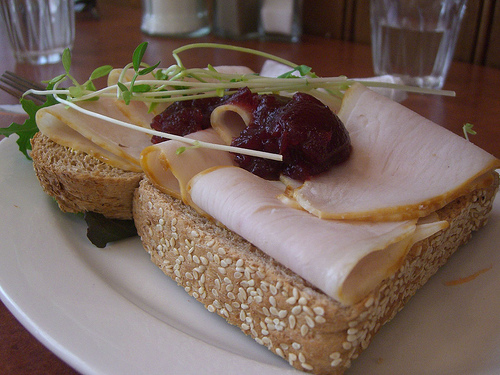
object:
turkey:
[154, 84, 305, 123]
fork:
[1, 65, 47, 104]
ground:
[318, 0, 363, 29]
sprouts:
[123, 62, 191, 101]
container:
[369, 0, 467, 90]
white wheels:
[0, 215, 195, 375]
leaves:
[15, 44, 198, 162]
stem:
[96, 42, 455, 160]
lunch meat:
[35, 60, 500, 306]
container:
[138, 0, 212, 39]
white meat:
[33, 303, 278, 375]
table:
[0, 0, 497, 375]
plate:
[0, 133, 497, 373]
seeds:
[141, 186, 461, 373]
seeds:
[33, 164, 50, 180]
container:
[257, 0, 304, 43]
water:
[372, 18, 445, 78]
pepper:
[216, 1, 258, 35]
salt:
[141, 0, 197, 34]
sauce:
[149, 86, 353, 181]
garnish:
[8, 43, 455, 163]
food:
[0, 43, 497, 372]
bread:
[29, 65, 498, 373]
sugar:
[140, 0, 203, 33]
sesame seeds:
[136, 187, 238, 330]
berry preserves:
[228, 91, 354, 181]